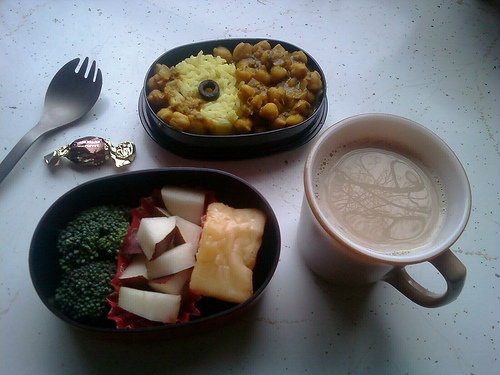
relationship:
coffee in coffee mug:
[322, 144, 441, 247] [296, 111, 472, 309]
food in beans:
[74, 210, 267, 293] [267, 65, 285, 78]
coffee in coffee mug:
[317, 144, 441, 248] [296, 111, 472, 309]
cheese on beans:
[188, 201, 265, 303] [267, 65, 285, 78]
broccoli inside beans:
[64, 214, 117, 309] [267, 65, 285, 78]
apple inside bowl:
[150, 220, 188, 280] [26, 174, 299, 312]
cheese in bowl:
[211, 210, 264, 276] [26, 174, 299, 312]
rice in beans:
[171, 59, 230, 123] [267, 65, 285, 78]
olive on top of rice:
[196, 79, 223, 105] [171, 59, 230, 123]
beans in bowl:
[257, 61, 290, 115] [141, 56, 341, 155]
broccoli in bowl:
[64, 214, 117, 309] [26, 168, 284, 335]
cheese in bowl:
[211, 210, 264, 276] [26, 168, 284, 335]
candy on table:
[38, 137, 139, 170] [27, 17, 499, 286]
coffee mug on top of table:
[296, 111, 472, 309] [27, 17, 499, 286]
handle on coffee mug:
[405, 258, 471, 308] [296, 111, 472, 309]